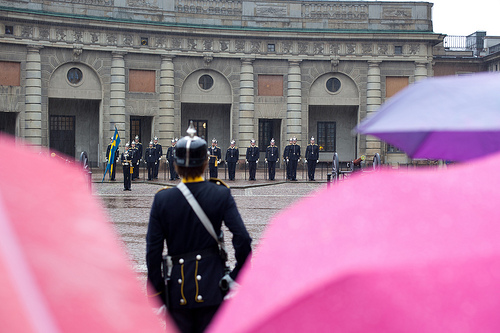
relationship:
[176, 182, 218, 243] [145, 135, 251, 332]
sash around man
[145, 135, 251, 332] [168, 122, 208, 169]
man wearing hat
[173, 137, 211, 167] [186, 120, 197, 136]
hat has hat/metal top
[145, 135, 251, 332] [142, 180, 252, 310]
man wearing jacket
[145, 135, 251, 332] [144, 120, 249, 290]
man wearing uniform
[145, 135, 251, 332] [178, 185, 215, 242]
man wearing strap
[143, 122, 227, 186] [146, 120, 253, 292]
head of person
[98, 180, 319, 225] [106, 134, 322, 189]
ground next to group men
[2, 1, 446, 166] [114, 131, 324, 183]
building behind people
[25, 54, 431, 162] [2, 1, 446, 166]
pillar on building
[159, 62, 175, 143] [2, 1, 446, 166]
pillar on building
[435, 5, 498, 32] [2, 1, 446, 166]
sky behind building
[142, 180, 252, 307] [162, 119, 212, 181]
man wearing helmet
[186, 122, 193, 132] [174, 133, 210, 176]
spike on helmet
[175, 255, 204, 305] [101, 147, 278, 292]
buttons on man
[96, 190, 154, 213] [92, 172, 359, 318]
water on ground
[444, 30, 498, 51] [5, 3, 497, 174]
fence at top of building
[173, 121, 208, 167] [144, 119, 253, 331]
hat on man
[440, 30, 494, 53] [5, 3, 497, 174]
fence on top of building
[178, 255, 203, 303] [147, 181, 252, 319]
buttons on suit